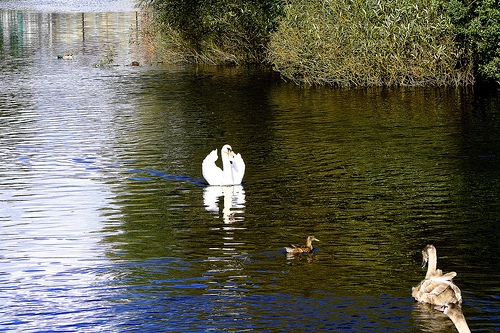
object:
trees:
[461, 0, 499, 85]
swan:
[197, 136, 251, 187]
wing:
[200, 147, 222, 186]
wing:
[228, 149, 246, 185]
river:
[0, 1, 499, 333]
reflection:
[199, 184, 248, 224]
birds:
[199, 144, 247, 186]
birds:
[282, 234, 320, 253]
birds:
[409, 245, 463, 307]